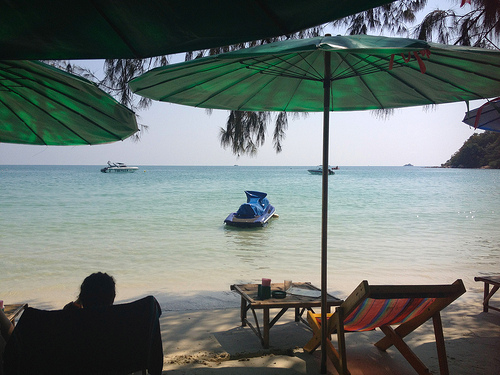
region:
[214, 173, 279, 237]
blue jet ski in water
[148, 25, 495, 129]
open green umbrella on beach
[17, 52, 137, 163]
open green umbrella on beach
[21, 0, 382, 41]
open green umbrella on beach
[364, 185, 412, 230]
clear green water in ocean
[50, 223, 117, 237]
clear green water in ocean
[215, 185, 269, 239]
blue and white jet ski in green ocean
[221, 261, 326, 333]
brown wooden table on beach sand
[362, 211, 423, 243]
clear green water in ocean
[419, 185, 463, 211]
clear green water in ocean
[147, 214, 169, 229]
clear green water in ocean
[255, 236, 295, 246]
clear green water in ocean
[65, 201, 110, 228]
clear green water in ocean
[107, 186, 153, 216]
white and blue ocean waves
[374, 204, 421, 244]
white and blue ocean waves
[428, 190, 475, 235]
white and blue ocean waves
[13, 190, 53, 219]
white and blue ocean waves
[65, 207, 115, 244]
white and blue ocean waves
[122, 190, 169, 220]
white and blue ocean waves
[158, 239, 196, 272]
white and blue ocean waves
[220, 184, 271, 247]
blue and white jet ski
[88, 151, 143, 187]
white boat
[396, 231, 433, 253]
white and blue ocean waves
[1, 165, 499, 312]
the boats on the water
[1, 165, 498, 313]
the large body of water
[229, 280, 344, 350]
the low wooden table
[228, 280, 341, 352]
the items on the wooden table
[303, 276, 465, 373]
the wooden chair with fabric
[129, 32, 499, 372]
the opened green umbrella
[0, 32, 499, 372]
the opened umbrellas on the shore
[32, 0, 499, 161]
the leaves hanging above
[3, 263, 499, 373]
the furniture on the shore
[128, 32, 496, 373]
the pole under the umbrella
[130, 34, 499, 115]
green cabana umbrella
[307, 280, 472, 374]
red, blue, and yellow chair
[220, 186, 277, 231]
blue and black jet ski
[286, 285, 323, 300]
white paper on table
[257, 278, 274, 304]
black cup on table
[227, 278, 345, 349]
table made of wood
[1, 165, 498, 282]
blue, clear water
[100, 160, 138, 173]
white boat on the left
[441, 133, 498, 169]
rock cliff near the water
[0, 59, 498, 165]
blue, clear sky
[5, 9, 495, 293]
pale blue sky over turquoise ocean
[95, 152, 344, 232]
boats and jet ski floating on the ocean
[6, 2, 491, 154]
branches hanging in back of open umbrellas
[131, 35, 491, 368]
umbrella over beach chair and table